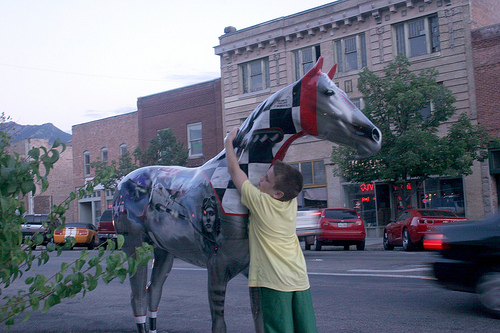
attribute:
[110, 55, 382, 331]
horse — statue, grey, sculpted, sculpture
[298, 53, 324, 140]
stripe — red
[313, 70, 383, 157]
face — grey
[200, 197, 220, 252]
person — pictured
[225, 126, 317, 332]
boy — hugging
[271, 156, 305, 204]
hair — brown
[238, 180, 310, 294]
shirt — white, yellow, cotton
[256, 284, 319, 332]
shorts — green, cotton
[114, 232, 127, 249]
leaf — green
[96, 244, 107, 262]
leaf — green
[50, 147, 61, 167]
leaf — green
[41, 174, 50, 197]
leaf — green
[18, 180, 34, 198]
leaf — green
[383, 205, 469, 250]
car — parked, red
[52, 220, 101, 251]
car — yellow, parked, orange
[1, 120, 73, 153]
mountain — distant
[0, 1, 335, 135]
sky — cloudy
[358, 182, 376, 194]
sign — lit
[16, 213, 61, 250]
car — silver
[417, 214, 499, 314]
car — black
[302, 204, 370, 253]
car — red